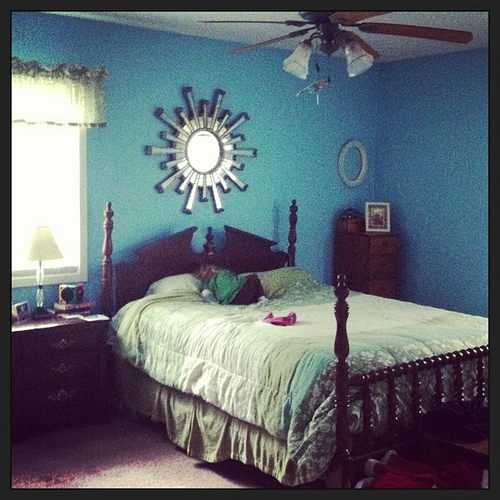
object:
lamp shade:
[25, 226, 63, 261]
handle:
[51, 362, 74, 374]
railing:
[349, 347, 490, 462]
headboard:
[112, 226, 288, 315]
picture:
[17, 303, 30, 320]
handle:
[52, 338, 78, 349]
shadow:
[193, 458, 326, 489]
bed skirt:
[114, 360, 297, 486]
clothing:
[262, 311, 297, 326]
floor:
[101, 433, 153, 467]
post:
[99, 201, 115, 316]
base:
[31, 269, 52, 320]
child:
[194, 264, 269, 307]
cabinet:
[333, 231, 397, 299]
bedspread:
[106, 284, 490, 456]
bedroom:
[11, 12, 488, 488]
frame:
[365, 201, 391, 232]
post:
[288, 199, 297, 267]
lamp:
[26, 227, 63, 320]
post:
[330, 273, 353, 465]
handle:
[47, 389, 76, 402]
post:
[362, 383, 375, 451]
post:
[386, 377, 400, 442]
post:
[412, 369, 420, 431]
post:
[435, 365, 446, 410]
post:
[453, 362, 465, 404]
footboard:
[330, 272, 488, 489]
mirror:
[186, 131, 220, 173]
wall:
[11, 9, 489, 321]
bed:
[98, 201, 489, 489]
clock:
[59, 284, 77, 304]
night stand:
[11, 308, 112, 443]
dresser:
[10, 309, 109, 446]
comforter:
[106, 264, 493, 483]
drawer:
[11, 352, 98, 391]